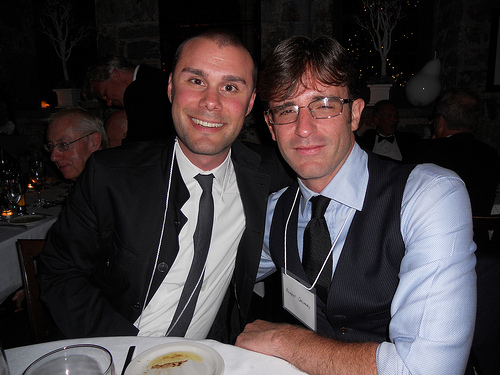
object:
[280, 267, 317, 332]
tag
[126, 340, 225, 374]
plate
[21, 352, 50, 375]
rim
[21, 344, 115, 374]
glass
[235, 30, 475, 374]
man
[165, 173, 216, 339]
tie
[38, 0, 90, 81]
tree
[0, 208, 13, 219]
candle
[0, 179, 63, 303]
table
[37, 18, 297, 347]
man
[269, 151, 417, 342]
vest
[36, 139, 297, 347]
suit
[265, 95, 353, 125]
glasses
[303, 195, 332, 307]
tie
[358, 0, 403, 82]
tree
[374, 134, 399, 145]
bow tie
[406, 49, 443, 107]
sculpture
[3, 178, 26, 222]
glass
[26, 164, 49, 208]
glass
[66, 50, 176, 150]
man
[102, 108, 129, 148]
man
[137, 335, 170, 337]
tag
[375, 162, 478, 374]
shirt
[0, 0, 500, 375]
wedding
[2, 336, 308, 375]
table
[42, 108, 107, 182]
man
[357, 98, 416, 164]
man